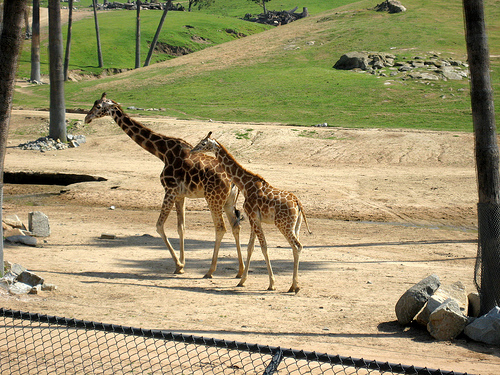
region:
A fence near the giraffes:
[1, 310, 457, 374]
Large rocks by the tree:
[397, 275, 497, 340]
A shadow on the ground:
[84, 238, 333, 293]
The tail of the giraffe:
[296, 203, 312, 235]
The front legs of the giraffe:
[238, 220, 273, 287]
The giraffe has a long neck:
[111, 107, 171, 159]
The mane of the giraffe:
[216, 140, 261, 175]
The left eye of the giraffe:
[91, 100, 106, 105]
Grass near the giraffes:
[0, 3, 495, 124]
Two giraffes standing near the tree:
[86, 93, 310, 295]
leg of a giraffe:
[282, 219, 307, 295]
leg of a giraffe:
[247, 211, 275, 293]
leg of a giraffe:
[232, 218, 257, 290]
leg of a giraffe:
[224, 190, 250, 275]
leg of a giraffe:
[197, 188, 231, 284]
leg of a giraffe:
[171, 186, 191, 278]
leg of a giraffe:
[151, 175, 191, 272]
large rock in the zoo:
[380, 265, 457, 327]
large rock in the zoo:
[27, 205, 52, 239]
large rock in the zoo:
[425, 299, 472, 338]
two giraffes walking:
[101, 95, 359, 291]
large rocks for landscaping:
[383, 240, 499, 341]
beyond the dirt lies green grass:
[113, 48, 489, 148]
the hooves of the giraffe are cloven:
[229, 273, 319, 295]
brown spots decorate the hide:
[180, 153, 220, 193]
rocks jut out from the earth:
[325, 40, 496, 103]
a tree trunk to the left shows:
[38, 15, 65, 157]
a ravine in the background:
[29, 18, 256, 107]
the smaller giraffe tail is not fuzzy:
[288, 186, 320, 240]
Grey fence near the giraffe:
[0, 306, 487, 374]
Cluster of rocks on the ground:
[389, 270, 498, 349]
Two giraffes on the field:
[82, 87, 312, 293]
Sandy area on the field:
[1, 108, 498, 374]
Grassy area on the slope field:
[0, 0, 499, 131]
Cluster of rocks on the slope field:
[332, 46, 476, 87]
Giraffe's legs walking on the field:
[152, 191, 245, 281]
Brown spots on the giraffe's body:
[168, 156, 213, 192]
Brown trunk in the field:
[43, 0, 68, 148]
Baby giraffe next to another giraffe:
[188, 129, 316, 297]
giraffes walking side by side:
[75, 76, 300, 297]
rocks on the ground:
[389, 272, 499, 351]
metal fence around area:
[1, 298, 341, 374]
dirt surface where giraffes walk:
[10, 113, 461, 356]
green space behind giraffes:
[111, 14, 476, 121]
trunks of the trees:
[4, 7, 83, 142]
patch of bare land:
[178, 47, 243, 63]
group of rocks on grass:
[340, 45, 480, 95]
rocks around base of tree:
[26, 121, 81, 149]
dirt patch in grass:
[146, 35, 186, 59]